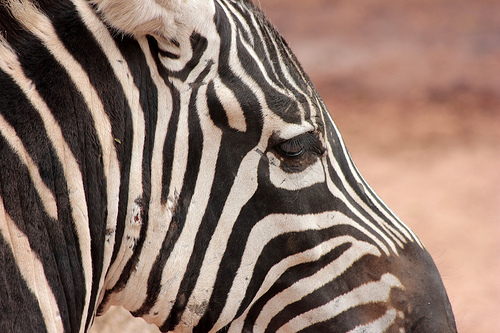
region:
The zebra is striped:
[0, 1, 457, 331]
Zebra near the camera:
[0, 1, 457, 331]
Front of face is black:
[402, 249, 456, 331]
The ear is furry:
[92, 0, 175, 45]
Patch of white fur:
[267, 215, 334, 225]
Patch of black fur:
[51, 226, 73, 293]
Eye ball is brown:
[279, 135, 304, 152]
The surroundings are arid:
[88, 1, 498, 330]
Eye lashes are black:
[285, 131, 317, 148]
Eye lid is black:
[276, 152, 308, 158]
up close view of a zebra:
[1, 7, 457, 329]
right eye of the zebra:
[271, 134, 319, 165]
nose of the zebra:
[367, 229, 464, 331]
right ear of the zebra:
[99, 1, 236, 78]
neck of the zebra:
[1, 3, 158, 332]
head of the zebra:
[105, 3, 459, 330]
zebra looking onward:
[6, 2, 454, 325]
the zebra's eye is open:
[263, 130, 344, 152]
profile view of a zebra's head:
[3, 0, 458, 330]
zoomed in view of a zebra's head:
[4, 4, 456, 331]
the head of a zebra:
[9, 0, 464, 329]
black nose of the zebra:
[378, 245, 457, 330]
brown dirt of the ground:
[395, 154, 475, 221]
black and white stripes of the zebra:
[132, 168, 244, 251]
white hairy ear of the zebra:
[101, 0, 212, 41]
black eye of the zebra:
[273, 125, 330, 178]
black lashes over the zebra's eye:
[285, 131, 315, 151]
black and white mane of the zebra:
[0, 5, 53, 57]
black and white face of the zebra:
[321, 156, 397, 270]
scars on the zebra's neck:
[82, 182, 195, 275]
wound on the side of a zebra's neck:
[128, 194, 142, 227]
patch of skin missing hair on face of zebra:
[186, 298, 207, 317]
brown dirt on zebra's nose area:
[350, 247, 423, 323]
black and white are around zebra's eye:
[255, 118, 327, 175]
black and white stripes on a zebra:
[12, 115, 123, 223]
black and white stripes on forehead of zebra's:
[221, 11, 327, 121]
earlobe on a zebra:
[82, 0, 224, 45]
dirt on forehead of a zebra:
[248, 13, 322, 103]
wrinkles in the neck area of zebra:
[24, 225, 166, 317]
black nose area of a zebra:
[408, 249, 453, 331]